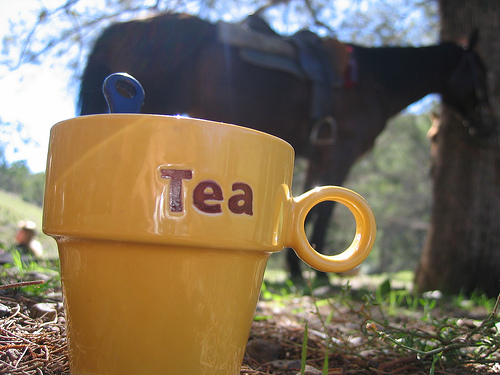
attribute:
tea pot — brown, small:
[41, 61, 380, 369]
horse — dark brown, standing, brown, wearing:
[70, 9, 497, 288]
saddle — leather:
[206, 19, 365, 147]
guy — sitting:
[4, 216, 44, 270]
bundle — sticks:
[5, 272, 58, 333]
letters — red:
[165, 153, 256, 224]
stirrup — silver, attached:
[311, 116, 339, 150]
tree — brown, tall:
[5, 8, 499, 315]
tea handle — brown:
[282, 178, 383, 280]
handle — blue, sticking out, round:
[102, 67, 148, 111]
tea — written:
[162, 155, 263, 216]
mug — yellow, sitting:
[35, 112, 382, 370]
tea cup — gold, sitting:
[40, 112, 376, 372]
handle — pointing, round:
[293, 183, 382, 279]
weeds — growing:
[269, 282, 498, 372]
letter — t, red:
[155, 164, 195, 220]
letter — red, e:
[193, 182, 226, 214]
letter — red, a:
[228, 181, 256, 214]